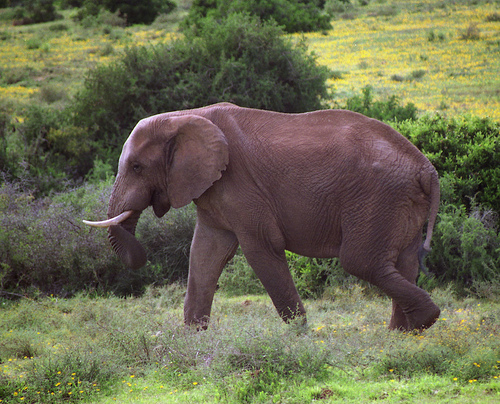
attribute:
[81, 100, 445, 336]
elephant — large, grey, walking, brown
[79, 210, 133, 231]
tusk — white, pointed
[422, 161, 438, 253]
tail — grey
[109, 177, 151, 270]
trunk — grey, curled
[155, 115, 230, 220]
ear — large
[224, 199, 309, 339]
leg — grey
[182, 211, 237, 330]
leg — grey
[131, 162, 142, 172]
eye — black, open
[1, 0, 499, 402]
grass — green, bright, wild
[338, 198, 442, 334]
leg — grey, lifted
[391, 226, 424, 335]
leg — grey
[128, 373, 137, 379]
flower — yellow, small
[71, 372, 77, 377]
flower — yellow, small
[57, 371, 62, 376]
flower — yellow, small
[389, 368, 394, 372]
flower — yellow, small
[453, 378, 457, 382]
flower — yellow, small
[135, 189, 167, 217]
mouth — open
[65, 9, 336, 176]
bush — green, large